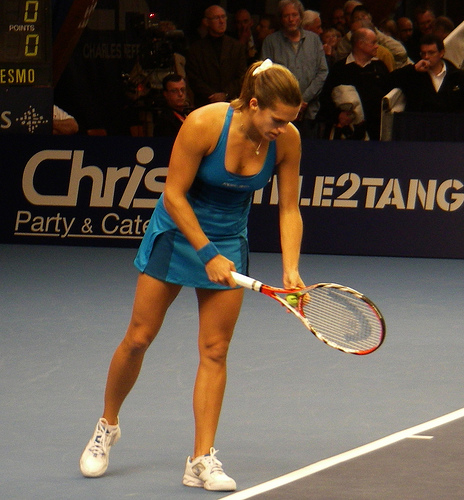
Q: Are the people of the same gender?
A: No, they are both male and female.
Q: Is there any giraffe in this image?
A: No, there are no giraffes.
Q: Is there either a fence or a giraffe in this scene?
A: No, there are no giraffes or fences.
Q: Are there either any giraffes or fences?
A: No, there are no giraffes or fences.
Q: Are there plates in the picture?
A: No, there are no plates.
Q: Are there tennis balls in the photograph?
A: Yes, there is a tennis ball.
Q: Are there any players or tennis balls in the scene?
A: Yes, there is a tennis ball.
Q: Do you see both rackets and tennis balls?
A: Yes, there are both a tennis ball and a racket.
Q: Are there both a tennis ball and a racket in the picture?
A: Yes, there are both a tennis ball and a racket.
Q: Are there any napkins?
A: No, there are no napkins.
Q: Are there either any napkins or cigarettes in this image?
A: No, there are no napkins or cigarettes.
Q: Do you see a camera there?
A: Yes, there is a camera.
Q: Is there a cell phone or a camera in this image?
A: Yes, there is a camera.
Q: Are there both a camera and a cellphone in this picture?
A: No, there is a camera but no cell phones.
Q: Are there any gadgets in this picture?
A: No, there are no gadgets.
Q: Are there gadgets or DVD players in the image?
A: No, there are no gadgets or DVD players.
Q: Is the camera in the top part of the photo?
A: Yes, the camera is in the top of the image.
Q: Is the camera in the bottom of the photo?
A: No, the camera is in the top of the image.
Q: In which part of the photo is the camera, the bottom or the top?
A: The camera is in the top of the image.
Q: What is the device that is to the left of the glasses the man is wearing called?
A: The device is a camera.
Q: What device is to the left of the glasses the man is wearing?
A: The device is a camera.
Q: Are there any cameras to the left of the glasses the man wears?
A: Yes, there is a camera to the left of the glasses.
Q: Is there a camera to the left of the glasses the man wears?
A: Yes, there is a camera to the left of the glasses.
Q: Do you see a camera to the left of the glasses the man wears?
A: Yes, there is a camera to the left of the glasses.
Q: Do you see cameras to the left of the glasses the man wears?
A: Yes, there is a camera to the left of the glasses.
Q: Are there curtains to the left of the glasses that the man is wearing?
A: No, there is a camera to the left of the glasses.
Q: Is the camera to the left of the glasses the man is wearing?
A: Yes, the camera is to the left of the glasses.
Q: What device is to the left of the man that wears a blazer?
A: The device is a camera.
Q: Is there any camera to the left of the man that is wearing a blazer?
A: Yes, there is a camera to the left of the man.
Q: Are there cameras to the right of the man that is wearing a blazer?
A: No, the camera is to the left of the man.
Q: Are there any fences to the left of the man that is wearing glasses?
A: No, there is a camera to the left of the man.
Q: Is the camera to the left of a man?
A: Yes, the camera is to the left of a man.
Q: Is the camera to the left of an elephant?
A: No, the camera is to the left of a man.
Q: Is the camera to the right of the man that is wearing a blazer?
A: No, the camera is to the left of the man.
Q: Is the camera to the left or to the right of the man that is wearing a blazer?
A: The camera is to the left of the man.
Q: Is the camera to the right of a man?
A: No, the camera is to the left of a man.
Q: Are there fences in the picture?
A: No, there are no fences.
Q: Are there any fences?
A: No, there are no fences.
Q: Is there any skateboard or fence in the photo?
A: No, there are no fences or skateboards.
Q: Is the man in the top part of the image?
A: Yes, the man is in the top of the image.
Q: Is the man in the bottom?
A: No, the man is in the top of the image.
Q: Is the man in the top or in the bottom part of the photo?
A: The man is in the top of the image.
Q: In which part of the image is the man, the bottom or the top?
A: The man is in the top of the image.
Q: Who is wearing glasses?
A: The man is wearing glasses.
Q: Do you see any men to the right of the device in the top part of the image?
A: Yes, there is a man to the right of the camera.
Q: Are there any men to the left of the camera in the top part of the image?
A: No, the man is to the right of the camera.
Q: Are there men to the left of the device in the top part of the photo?
A: No, the man is to the right of the camera.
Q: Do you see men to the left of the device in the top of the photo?
A: No, the man is to the right of the camera.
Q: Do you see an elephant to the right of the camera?
A: No, there is a man to the right of the camera.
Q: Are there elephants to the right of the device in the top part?
A: No, there is a man to the right of the camera.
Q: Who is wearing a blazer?
A: The man is wearing a blazer.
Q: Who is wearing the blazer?
A: The man is wearing a blazer.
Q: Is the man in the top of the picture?
A: Yes, the man is in the top of the image.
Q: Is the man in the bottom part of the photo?
A: No, the man is in the top of the image.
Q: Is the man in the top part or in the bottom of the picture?
A: The man is in the top of the image.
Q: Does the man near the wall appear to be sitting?
A: Yes, the man is sitting.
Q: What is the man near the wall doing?
A: The man is sitting.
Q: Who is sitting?
A: The man is sitting.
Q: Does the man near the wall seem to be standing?
A: No, the man is sitting.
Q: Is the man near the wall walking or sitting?
A: The man is sitting.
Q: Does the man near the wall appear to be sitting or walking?
A: The man is sitting.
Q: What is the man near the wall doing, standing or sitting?
A: The man is sitting.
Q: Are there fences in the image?
A: No, there are no fences.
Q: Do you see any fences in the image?
A: No, there are no fences.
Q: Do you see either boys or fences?
A: No, there are no fences or boys.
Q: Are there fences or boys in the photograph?
A: No, there are no fences or boys.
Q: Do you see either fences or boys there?
A: No, there are no fences or boys.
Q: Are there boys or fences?
A: No, there are no fences or boys.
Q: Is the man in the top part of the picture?
A: Yes, the man is in the top of the image.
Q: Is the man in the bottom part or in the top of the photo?
A: The man is in the top of the image.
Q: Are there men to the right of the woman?
A: Yes, there is a man to the right of the woman.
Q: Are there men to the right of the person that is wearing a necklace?
A: Yes, there is a man to the right of the woman.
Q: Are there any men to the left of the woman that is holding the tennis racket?
A: No, the man is to the right of the woman.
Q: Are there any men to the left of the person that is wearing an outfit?
A: No, the man is to the right of the woman.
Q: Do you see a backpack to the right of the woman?
A: No, there is a man to the right of the woman.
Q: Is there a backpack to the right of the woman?
A: No, there is a man to the right of the woman.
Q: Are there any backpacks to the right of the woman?
A: No, there is a man to the right of the woman.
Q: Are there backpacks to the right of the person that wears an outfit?
A: No, there is a man to the right of the woman.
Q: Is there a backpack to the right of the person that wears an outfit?
A: No, there is a man to the right of the woman.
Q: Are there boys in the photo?
A: No, there are no boys.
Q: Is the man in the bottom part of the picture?
A: No, the man is in the top of the image.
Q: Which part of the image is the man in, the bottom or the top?
A: The man is in the top of the image.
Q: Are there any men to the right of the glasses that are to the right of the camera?
A: Yes, there is a man to the right of the glasses.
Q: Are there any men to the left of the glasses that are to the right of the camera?
A: No, the man is to the right of the glasses.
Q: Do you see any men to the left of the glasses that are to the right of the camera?
A: No, the man is to the right of the glasses.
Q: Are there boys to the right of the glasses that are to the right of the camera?
A: No, there is a man to the right of the glasses.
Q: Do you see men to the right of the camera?
A: Yes, there is a man to the right of the camera.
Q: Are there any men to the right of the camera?
A: Yes, there is a man to the right of the camera.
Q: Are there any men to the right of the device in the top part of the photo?
A: Yes, there is a man to the right of the camera.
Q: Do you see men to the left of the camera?
A: No, the man is to the right of the camera.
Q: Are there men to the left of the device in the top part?
A: No, the man is to the right of the camera.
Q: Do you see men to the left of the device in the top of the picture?
A: No, the man is to the right of the camera.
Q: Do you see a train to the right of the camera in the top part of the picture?
A: No, there is a man to the right of the camera.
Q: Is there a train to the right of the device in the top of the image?
A: No, there is a man to the right of the camera.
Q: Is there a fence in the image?
A: No, there are no fences.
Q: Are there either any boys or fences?
A: No, there are no fences or boys.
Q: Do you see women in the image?
A: Yes, there is a woman.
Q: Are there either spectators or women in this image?
A: Yes, there is a woman.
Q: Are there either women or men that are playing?
A: Yes, the woman is playing.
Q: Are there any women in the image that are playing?
A: Yes, there is a woman that is playing.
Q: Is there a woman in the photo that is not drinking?
A: Yes, there is a woman that is playing.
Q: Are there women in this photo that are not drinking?
A: Yes, there is a woman that is playing.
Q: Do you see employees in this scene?
A: No, there are no employees.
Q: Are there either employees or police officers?
A: No, there are no employees or police officers.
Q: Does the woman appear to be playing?
A: Yes, the woman is playing.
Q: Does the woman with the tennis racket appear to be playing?
A: Yes, the woman is playing.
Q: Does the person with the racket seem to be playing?
A: Yes, the woman is playing.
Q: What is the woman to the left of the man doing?
A: The woman is playing.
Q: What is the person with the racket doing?
A: The woman is playing.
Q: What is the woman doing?
A: The woman is playing.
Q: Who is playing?
A: The woman is playing.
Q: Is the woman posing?
A: No, the woman is playing.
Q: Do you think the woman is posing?
A: No, the woman is playing.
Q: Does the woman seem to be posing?
A: No, the woman is playing.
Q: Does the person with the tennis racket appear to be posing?
A: No, the woman is playing.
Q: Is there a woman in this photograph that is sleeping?
A: No, there is a woman but she is playing.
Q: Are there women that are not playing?
A: No, there is a woman but she is playing.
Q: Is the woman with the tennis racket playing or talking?
A: The woman is playing.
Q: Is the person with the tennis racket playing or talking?
A: The woman is playing.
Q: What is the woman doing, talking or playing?
A: The woman is playing.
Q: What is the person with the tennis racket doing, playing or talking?
A: The woman is playing.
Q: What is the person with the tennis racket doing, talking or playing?
A: The woman is playing.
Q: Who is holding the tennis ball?
A: The woman is holding the tennis ball.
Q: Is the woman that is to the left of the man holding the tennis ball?
A: Yes, the woman is holding the tennis ball.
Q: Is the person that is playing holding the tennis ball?
A: Yes, the woman is holding the tennis ball.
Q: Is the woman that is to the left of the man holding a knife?
A: No, the woman is holding the tennis ball.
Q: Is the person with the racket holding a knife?
A: No, the woman is holding the tennis ball.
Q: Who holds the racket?
A: The woman holds the tennis racket.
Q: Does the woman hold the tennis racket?
A: Yes, the woman holds the tennis racket.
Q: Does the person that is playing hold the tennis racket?
A: Yes, the woman holds the tennis racket.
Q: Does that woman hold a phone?
A: No, the woman holds the tennis racket.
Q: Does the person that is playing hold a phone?
A: No, the woman holds the tennis racket.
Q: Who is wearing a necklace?
A: The woman is wearing a necklace.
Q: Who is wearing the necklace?
A: The woman is wearing a necklace.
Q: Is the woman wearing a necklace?
A: Yes, the woman is wearing a necklace.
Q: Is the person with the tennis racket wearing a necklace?
A: Yes, the woman is wearing a necklace.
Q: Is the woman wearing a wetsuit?
A: No, the woman is wearing a necklace.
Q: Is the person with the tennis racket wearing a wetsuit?
A: No, the woman is wearing a necklace.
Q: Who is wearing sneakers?
A: The woman is wearing sneakers.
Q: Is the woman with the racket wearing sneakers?
A: Yes, the woman is wearing sneakers.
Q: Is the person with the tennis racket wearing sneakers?
A: Yes, the woman is wearing sneakers.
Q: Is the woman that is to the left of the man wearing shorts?
A: No, the woman is wearing sneakers.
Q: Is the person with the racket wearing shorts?
A: No, the woman is wearing sneakers.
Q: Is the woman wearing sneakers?
A: Yes, the woman is wearing sneakers.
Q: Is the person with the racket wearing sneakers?
A: Yes, the woman is wearing sneakers.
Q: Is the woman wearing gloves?
A: No, the woman is wearing sneakers.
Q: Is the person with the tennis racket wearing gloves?
A: No, the woman is wearing sneakers.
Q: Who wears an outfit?
A: The woman wears an outfit.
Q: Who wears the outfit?
A: The woman wears an outfit.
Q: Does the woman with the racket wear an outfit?
A: Yes, the woman wears an outfit.